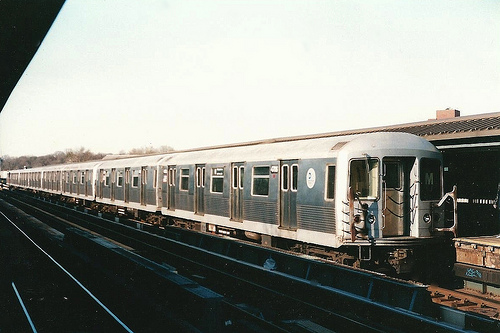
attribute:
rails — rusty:
[14, 185, 499, 327]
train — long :
[5, 130, 462, 272]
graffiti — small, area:
[459, 254, 499, 287]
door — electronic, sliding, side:
[229, 160, 242, 222]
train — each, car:
[28, 82, 493, 255]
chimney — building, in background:
[429, 101, 463, 124]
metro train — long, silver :
[1, 131, 457, 274]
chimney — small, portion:
[429, 102, 465, 123]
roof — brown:
[101, 110, 498, 140]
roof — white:
[5, 132, 437, 166]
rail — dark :
[3, 213, 145, 325]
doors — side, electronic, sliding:
[194, 163, 204, 212]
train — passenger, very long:
[8, 123, 480, 290]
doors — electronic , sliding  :
[252, 150, 350, 258]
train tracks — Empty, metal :
[2, 182, 497, 329]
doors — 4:
[224, 151, 304, 235]